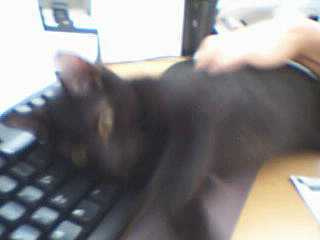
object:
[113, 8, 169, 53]
wall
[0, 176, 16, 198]
keyboard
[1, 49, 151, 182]
head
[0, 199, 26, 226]
keyboard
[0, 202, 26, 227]
buttons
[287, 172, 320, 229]
paper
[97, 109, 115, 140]
eye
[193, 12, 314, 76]
blurry hand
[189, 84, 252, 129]
fur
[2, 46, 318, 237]
black cat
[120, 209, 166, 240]
paw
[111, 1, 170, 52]
moped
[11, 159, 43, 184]
keyboard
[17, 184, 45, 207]
keyboard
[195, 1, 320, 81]
person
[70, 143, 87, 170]
eye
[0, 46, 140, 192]
branches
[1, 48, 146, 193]
yellow flowers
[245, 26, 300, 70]
fingers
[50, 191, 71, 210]
keyboard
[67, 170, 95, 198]
keyboard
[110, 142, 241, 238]
cat arms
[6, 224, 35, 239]
buttons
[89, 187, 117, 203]
keyboard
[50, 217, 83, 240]
buttons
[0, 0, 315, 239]
picture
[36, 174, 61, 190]
keyboard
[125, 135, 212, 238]
arm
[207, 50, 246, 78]
fingers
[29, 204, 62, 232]
buttons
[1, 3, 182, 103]
background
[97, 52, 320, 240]
desk